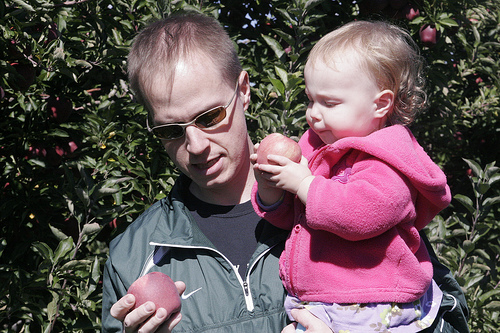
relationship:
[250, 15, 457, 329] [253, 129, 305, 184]
baby has red apple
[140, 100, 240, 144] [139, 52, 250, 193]
sunglasses on face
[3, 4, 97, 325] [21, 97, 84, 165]
tree of apple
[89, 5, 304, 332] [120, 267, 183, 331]
man looking apple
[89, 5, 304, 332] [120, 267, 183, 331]
man holding apple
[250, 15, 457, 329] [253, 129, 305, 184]
girl holding an apple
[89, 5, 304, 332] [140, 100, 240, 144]
man has sunglasses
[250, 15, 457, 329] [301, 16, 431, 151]
girl has curly hair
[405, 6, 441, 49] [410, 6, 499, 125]
apples hanging on plant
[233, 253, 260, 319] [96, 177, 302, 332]
zipper on pullover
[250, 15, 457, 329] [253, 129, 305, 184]
baby holding apple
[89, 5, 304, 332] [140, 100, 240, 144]
man wearing sunglasses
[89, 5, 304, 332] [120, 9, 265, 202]
man with blond hair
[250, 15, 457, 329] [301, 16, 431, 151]
baby with blond hair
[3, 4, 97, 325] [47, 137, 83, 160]
tree has apples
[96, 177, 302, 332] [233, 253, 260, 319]
jacket has white zipper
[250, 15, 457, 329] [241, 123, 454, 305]
baby wearing pink jacket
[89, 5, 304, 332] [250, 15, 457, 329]
man holding baby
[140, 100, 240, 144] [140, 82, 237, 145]
glasses has glasses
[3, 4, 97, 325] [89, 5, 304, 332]
tree behind man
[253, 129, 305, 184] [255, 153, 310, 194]
apple in hand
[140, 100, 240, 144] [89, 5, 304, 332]
glasses on man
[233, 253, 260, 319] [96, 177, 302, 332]
zipper located on jacket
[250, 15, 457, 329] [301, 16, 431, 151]
baby has blond hair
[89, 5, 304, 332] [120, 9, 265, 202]
man has thinning hair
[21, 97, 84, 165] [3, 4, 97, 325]
apple in tree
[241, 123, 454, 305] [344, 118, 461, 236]
jacket has a hood